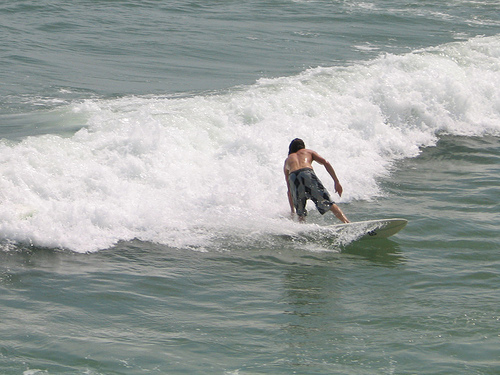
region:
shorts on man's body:
[288, 169, 335, 214]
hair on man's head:
[287, 138, 306, 153]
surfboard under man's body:
[328, 215, 407, 248]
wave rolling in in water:
[0, 28, 498, 250]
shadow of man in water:
[290, 256, 335, 334]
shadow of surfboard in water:
[357, 240, 400, 269]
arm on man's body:
[315, 151, 344, 194]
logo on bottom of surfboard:
[363, 228, 380, 238]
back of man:
[289, 149, 312, 169]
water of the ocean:
[0, 2, 495, 373]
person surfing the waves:
[220, 115, 416, 268]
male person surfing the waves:
[210, 113, 432, 291]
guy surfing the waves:
[221, 118, 436, 294]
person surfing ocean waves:
[210, 116, 431, 274]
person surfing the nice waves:
[201, 117, 437, 290]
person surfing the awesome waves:
[188, 101, 423, 326]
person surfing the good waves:
[200, 112, 442, 278]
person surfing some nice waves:
[197, 106, 416, 275]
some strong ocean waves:
[40, 95, 247, 262]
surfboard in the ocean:
[237, 210, 413, 257]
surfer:
[275, 133, 344, 241]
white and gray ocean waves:
[92, 120, 133, 164]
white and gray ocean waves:
[299, 321, 332, 343]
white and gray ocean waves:
[420, 303, 443, 320]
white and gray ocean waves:
[142, 188, 198, 250]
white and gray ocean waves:
[32, 252, 62, 299]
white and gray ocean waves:
[139, 108, 192, 170]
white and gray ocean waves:
[364, 45, 422, 104]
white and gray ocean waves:
[170, 114, 210, 169]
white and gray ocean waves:
[69, 99, 122, 181]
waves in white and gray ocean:
[110, 108, 182, 150]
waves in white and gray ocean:
[97, 156, 147, 208]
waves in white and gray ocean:
[375, 301, 423, 333]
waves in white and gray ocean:
[170, 282, 247, 350]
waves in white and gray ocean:
[68, 286, 156, 341]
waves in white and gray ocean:
[352, 105, 439, 133]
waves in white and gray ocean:
[164, 116, 216, 154]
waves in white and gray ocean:
[68, 83, 159, 157]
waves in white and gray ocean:
[80, 168, 178, 245]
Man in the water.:
[271, 114, 381, 259]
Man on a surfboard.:
[205, 114, 419, 322]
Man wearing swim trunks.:
[228, 95, 475, 330]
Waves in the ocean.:
[48, 64, 353, 347]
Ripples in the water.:
[121, 227, 460, 372]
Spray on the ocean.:
[303, 44, 460, 243]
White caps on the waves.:
[103, 49, 354, 281]